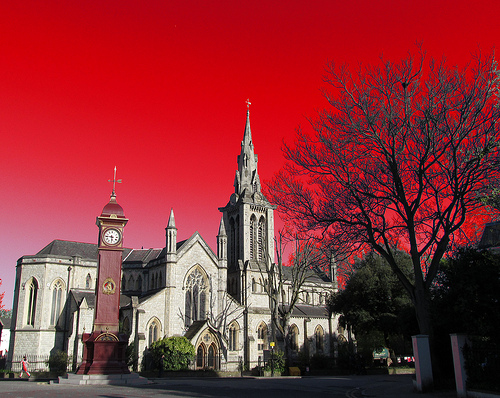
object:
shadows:
[290, 331, 371, 375]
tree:
[325, 249, 415, 377]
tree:
[431, 240, 496, 382]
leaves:
[328, 239, 426, 331]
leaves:
[434, 235, 499, 325]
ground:
[388, 81, 437, 106]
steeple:
[223, 99, 273, 206]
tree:
[286, 70, 474, 239]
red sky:
[0, 3, 500, 291]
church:
[11, 97, 360, 380]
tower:
[82, 167, 133, 373]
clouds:
[0, 0, 497, 309]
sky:
[4, 1, 499, 260]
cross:
[245, 99, 251, 110]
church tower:
[215, 98, 281, 275]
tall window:
[48, 282, 64, 327]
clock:
[102, 228, 121, 246]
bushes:
[140, 334, 195, 372]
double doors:
[195, 341, 218, 369]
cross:
[108, 165, 123, 196]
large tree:
[262, 35, 498, 388]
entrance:
[194, 333, 220, 372]